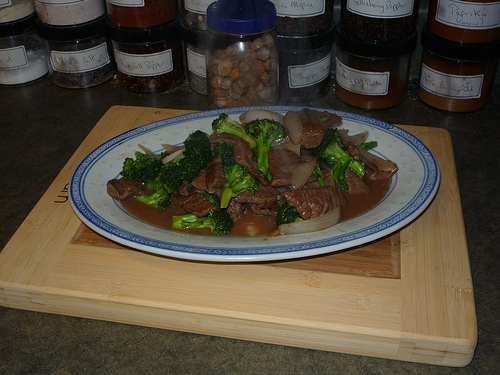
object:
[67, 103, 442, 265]
plate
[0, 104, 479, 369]
board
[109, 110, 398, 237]
food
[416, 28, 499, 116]
jars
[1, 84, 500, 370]
counter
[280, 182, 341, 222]
beef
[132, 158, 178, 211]
broccoli